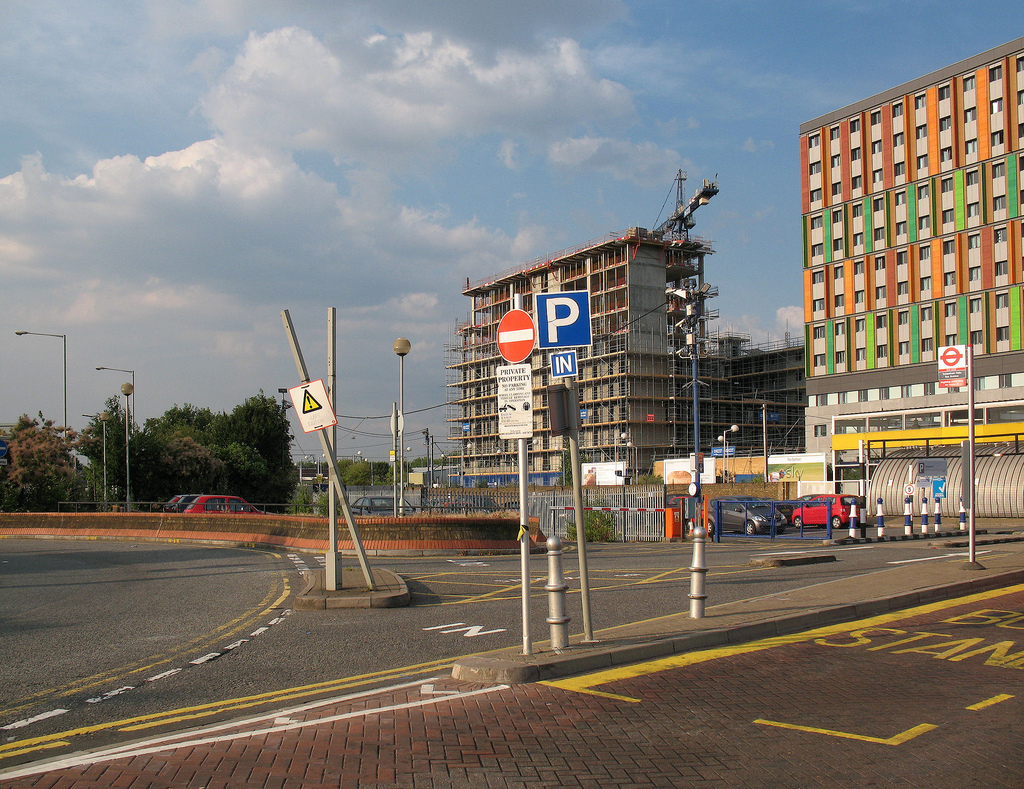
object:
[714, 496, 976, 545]
line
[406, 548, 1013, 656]
median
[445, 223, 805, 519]
building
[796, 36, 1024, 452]
apartment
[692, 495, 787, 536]
cars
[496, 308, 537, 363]
traffic sign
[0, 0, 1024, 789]
picture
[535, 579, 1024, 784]
spot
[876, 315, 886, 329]
window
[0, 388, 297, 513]
trees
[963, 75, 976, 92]
window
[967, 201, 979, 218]
window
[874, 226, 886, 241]
window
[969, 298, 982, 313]
window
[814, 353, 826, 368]
window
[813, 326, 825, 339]
window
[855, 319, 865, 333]
window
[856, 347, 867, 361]
window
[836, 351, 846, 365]
window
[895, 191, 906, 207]
window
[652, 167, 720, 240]
sky crane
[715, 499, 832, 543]
gate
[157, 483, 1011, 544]
parking area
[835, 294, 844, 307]
window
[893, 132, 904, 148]
window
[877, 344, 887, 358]
window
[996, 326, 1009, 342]
window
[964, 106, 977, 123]
window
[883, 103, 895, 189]
trim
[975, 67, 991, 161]
trim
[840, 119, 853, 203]
trim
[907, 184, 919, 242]
trim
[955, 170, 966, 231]
trim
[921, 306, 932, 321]
window